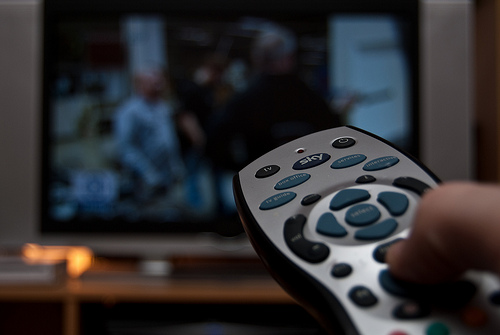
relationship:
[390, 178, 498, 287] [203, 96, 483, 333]
finger on remote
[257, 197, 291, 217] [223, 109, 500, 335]
button on remote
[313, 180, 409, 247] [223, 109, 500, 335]
button on remote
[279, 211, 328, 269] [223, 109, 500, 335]
button on remote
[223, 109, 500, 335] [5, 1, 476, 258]
remote aimed at flatscreen tv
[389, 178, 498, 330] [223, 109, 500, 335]
person holding remote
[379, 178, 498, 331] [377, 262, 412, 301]
person pressing button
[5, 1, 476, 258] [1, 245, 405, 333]
flatscreen tv on stand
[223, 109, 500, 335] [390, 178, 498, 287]
remote in finger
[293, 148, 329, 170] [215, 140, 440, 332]
button on remote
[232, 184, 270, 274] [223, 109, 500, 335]
border on remote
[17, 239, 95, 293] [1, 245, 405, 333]
light on stand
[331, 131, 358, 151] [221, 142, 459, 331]
power button on remote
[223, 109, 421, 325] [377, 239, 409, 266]
remote pushing button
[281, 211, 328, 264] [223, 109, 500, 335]
button on remote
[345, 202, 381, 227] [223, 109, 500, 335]
button on remote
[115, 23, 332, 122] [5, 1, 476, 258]
people on flatscreen tv